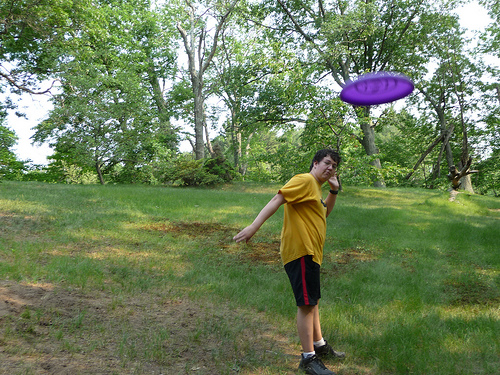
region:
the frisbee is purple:
[331, 63, 424, 110]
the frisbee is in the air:
[339, 73, 417, 115]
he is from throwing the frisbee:
[240, 147, 365, 373]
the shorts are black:
[281, 258, 327, 307]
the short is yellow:
[275, 178, 336, 262]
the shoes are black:
[296, 346, 343, 373]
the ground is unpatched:
[173, 211, 233, 249]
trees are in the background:
[23, 78, 492, 180]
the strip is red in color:
[281, 262, 324, 309]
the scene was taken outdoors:
[6, 61, 495, 373]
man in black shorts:
[268, 210, 375, 301]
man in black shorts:
[271, 175, 343, 268]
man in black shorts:
[272, 167, 309, 245]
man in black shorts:
[268, 180, 318, 307]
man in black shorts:
[270, 189, 335, 365]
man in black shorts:
[279, 240, 315, 347]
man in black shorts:
[248, 182, 294, 329]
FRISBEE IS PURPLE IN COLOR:
[332, 72, 418, 112]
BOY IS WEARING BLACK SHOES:
[283, 337, 348, 374]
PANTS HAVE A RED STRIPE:
[273, 257, 379, 322]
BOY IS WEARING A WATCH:
[323, 172, 353, 209]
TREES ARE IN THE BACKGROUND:
[2, 2, 499, 190]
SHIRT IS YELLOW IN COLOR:
[268, 157, 350, 279]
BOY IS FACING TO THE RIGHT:
[235, 147, 365, 373]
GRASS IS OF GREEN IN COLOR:
[3, 185, 243, 344]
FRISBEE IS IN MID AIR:
[318, 67, 415, 118]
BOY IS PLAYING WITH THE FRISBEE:
[208, 142, 397, 362]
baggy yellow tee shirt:
[258, 169, 338, 274]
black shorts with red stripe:
[265, 249, 342, 321]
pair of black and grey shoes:
[280, 332, 353, 374]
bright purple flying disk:
[320, 66, 427, 124]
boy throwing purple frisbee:
[223, 63, 428, 369]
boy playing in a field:
[7, 5, 495, 370]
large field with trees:
[3, 1, 228, 371]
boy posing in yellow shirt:
[215, 134, 364, 374]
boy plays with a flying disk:
[213, 56, 450, 371]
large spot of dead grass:
[3, 260, 273, 374]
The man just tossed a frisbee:
[221, 54, 426, 374]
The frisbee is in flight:
[301, 49, 431, 132]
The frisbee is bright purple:
[283, 50, 431, 123]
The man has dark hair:
[293, 138, 352, 194]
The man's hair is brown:
[289, 135, 366, 179]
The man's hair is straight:
[293, 145, 353, 193]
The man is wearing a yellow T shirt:
[251, 154, 343, 277]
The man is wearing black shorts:
[272, 238, 335, 311]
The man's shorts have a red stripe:
[268, 237, 348, 310]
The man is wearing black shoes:
[274, 328, 356, 370]